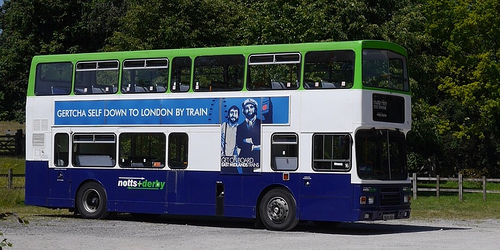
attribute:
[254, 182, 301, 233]
wheel — silver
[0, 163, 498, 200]
fence — wood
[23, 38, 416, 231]
bus — green, white, blue, double-decker, road, double decker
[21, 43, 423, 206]
bus — blue, white, green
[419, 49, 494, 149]
trees — lush, green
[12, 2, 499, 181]
trees — green, full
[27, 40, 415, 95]
bus top — green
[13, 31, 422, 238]
bus — double-decker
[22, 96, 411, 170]
middle — white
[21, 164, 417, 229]
bottom — blue